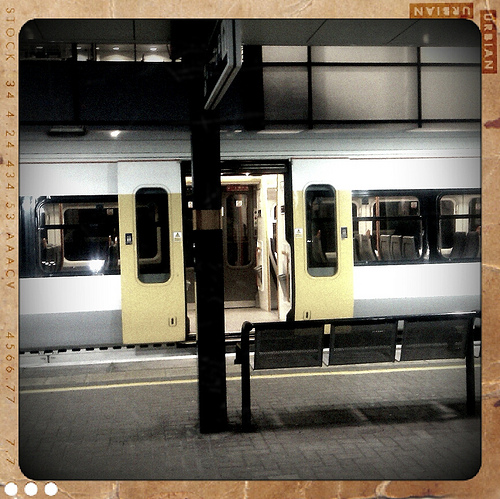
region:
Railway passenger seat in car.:
[380, 233, 422, 261]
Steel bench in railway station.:
[243, 310, 482, 417]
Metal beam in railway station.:
[196, 60, 227, 432]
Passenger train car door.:
[121, 164, 188, 344]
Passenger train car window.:
[349, 195, 434, 265]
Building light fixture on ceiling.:
[108, 47, 123, 54]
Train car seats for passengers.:
[378, 235, 420, 259]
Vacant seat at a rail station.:
[238, 310, 477, 422]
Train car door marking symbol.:
[173, 230, 182, 239]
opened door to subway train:
[101, 149, 313, 352]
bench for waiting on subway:
[236, 298, 497, 447]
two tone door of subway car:
[113, 150, 194, 348]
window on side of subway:
[353, 179, 488, 281]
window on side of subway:
[21, 186, 178, 315]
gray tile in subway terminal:
[96, 406, 201, 477]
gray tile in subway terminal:
[254, 437, 398, 474]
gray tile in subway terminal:
[293, 383, 419, 400]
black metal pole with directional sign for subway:
[186, 16, 247, 433]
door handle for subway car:
[121, 221, 140, 256]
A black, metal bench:
[221, 309, 493, 421]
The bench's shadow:
[203, 387, 485, 434]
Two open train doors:
[102, 153, 384, 348]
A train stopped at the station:
[22, 91, 479, 482]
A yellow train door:
[285, 151, 362, 338]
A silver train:
[16, 119, 479, 345]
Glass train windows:
[319, 186, 494, 265]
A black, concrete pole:
[176, 37, 244, 439]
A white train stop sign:
[170, 19, 261, 119]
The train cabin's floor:
[186, 283, 300, 355]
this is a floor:
[210, 433, 427, 478]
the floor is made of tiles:
[45, 393, 180, 474]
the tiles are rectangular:
[263, 438, 376, 467]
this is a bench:
[238, 311, 480, 407]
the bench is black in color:
[235, 311, 477, 417]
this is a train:
[31, 147, 183, 344]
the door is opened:
[226, 173, 286, 322]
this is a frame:
[0, 0, 460, 14]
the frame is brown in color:
[481, 171, 499, 411]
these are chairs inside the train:
[383, 238, 418, 258]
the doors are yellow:
[113, 202, 467, 349]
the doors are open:
[96, 145, 427, 354]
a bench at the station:
[213, 308, 498, 396]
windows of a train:
[20, 173, 159, 399]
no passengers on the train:
[346, 223, 435, 285]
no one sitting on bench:
[260, 308, 481, 428]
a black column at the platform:
[134, 328, 273, 483]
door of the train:
[226, 183, 318, 378]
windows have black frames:
[381, 181, 498, 294]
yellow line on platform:
[49, 368, 204, 447]